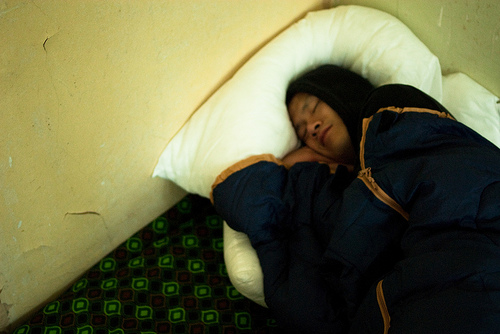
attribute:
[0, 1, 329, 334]
wall — battered, yellow, plaster, cracked, dirty, tan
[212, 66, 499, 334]
woman — sleeping, girl, person, wearing robe, smiling, lady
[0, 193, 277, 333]
carpet — green, black, weird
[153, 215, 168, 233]
pattern — green, outer, diamond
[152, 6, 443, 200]
pillow — white, fluffy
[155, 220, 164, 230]
circle — inner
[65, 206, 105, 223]
hole — large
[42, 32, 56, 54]
hole — small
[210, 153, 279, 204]
strip — light, tan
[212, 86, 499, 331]
coat — black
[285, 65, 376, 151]
hair — straight, black, long, dark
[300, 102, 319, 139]
eyes — closed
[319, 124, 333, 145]
lipstick — red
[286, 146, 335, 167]
hand — curled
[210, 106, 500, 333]
bag — blue, sleeping bag, zip up, brown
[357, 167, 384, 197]
zipper — tan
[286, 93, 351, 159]
face — sleeping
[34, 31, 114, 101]
paint — chipped, cracked